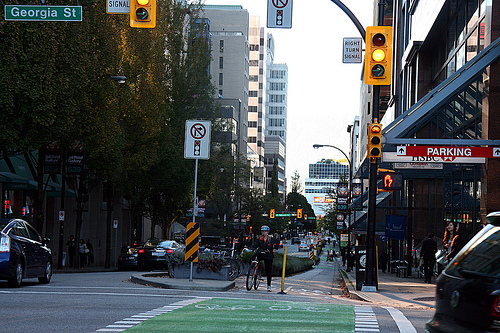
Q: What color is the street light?
A: Yellow.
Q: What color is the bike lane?
A: Green.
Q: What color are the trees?
A: Green.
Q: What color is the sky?
A: White.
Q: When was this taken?
A: Daytime.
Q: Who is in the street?
A: A bicyclist.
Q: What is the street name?
A: Georgia St.